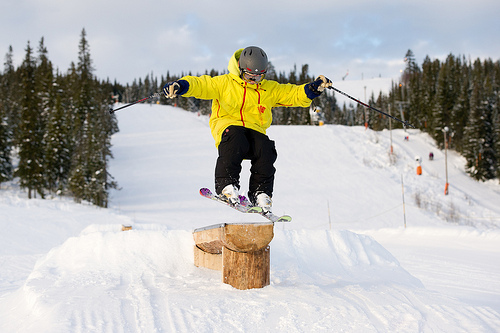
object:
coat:
[176, 49, 315, 146]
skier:
[162, 46, 335, 222]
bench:
[192, 221, 276, 291]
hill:
[24, 221, 426, 332]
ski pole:
[327, 85, 416, 131]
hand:
[307, 75, 333, 93]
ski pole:
[108, 85, 180, 115]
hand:
[162, 82, 182, 99]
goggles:
[241, 72, 266, 84]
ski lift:
[313, 73, 452, 199]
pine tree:
[1, 26, 120, 208]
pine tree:
[353, 46, 500, 178]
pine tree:
[113, 63, 389, 130]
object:
[414, 156, 423, 175]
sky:
[1, 1, 499, 82]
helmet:
[239, 45, 269, 74]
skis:
[196, 185, 291, 223]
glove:
[312, 75, 333, 92]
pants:
[214, 124, 277, 207]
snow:
[0, 103, 495, 332]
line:
[240, 81, 248, 127]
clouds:
[157, 24, 197, 49]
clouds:
[350, 52, 402, 66]